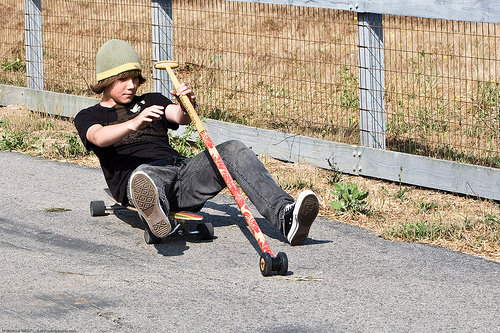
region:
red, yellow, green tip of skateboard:
[177, 210, 219, 245]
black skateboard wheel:
[86, 199, 113, 217]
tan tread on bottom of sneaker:
[126, 170, 177, 240]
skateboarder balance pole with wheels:
[153, 57, 295, 284]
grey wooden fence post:
[347, 5, 397, 181]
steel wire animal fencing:
[183, 11, 362, 153]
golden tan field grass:
[192, 17, 343, 75]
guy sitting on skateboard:
[75, 155, 208, 245]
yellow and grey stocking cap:
[71, 36, 146, 85]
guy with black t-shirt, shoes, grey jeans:
[78, 92, 318, 250]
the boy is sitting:
[69, 18, 319, 297]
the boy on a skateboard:
[59, 25, 357, 320]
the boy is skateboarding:
[57, 30, 336, 305]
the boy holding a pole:
[56, 27, 336, 266]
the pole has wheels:
[156, 53, 297, 277]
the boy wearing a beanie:
[29, 33, 341, 295]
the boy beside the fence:
[62, 23, 331, 280]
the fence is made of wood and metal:
[294, 3, 491, 194]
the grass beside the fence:
[365, 187, 460, 229]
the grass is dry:
[401, 190, 447, 240]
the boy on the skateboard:
[70, 21, 341, 283]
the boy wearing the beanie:
[51, 29, 356, 276]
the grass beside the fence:
[396, 187, 483, 244]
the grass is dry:
[378, 198, 462, 233]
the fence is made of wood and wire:
[6, 5, 498, 206]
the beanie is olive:
[82, 30, 147, 74]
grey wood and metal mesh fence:
[151, 3, 498, 170]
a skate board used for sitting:
[91, 189, 213, 249]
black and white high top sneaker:
[275, 178, 319, 251]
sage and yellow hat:
[86, 35, 145, 80]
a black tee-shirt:
[71, 99, 195, 196]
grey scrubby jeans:
[138, 121, 285, 236]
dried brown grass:
[173, 8, 370, 85]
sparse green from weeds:
[1, 111, 86, 158]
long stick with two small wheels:
[153, 53, 293, 281]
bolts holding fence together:
[342, 141, 370, 182]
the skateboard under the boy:
[88, 182, 215, 247]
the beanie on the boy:
[95, 37, 141, 75]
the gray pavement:
[75, 270, 281, 331]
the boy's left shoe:
[284, 191, 315, 242]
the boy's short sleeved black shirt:
[70, 93, 195, 185]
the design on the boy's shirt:
[109, 107, 154, 144]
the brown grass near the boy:
[265, 159, 312, 185]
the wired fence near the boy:
[194, 10, 475, 162]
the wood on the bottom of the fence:
[247, 130, 364, 165]